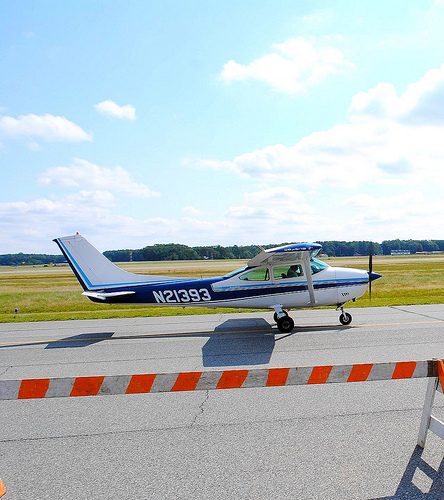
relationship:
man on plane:
[288, 264, 300, 279] [53, 233, 384, 334]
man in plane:
[288, 264, 300, 279] [53, 233, 384, 334]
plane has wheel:
[53, 233, 384, 334] [339, 313, 353, 325]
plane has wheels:
[53, 233, 384, 334] [272, 311, 295, 334]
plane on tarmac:
[53, 233, 384, 334] [2, 308, 444, 500]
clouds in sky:
[1, 99, 139, 146] [3, 2, 213, 100]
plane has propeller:
[53, 233, 384, 334] [370, 241, 373, 294]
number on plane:
[164, 288, 211, 303] [53, 233, 384, 334]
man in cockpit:
[288, 264, 300, 279] [272, 263, 306, 281]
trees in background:
[105, 243, 254, 262] [30, 224, 430, 269]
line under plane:
[2, 318, 443, 347] [53, 233, 384, 334]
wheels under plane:
[272, 311, 295, 334] [53, 233, 384, 334]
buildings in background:
[390, 248, 413, 257] [30, 224, 430, 269]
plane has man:
[53, 233, 384, 334] [288, 264, 300, 279]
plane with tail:
[53, 233, 384, 334] [53, 235, 140, 290]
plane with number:
[53, 233, 384, 334] [164, 288, 211, 303]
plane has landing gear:
[53, 233, 384, 334] [270, 304, 355, 333]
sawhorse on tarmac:
[416, 357, 443, 449] [2, 308, 444, 500]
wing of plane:
[246, 242, 323, 269] [53, 233, 384, 334]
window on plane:
[238, 267, 271, 283] [53, 233, 384, 334]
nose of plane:
[368, 273, 382, 283] [53, 233, 384, 334]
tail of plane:
[53, 235, 140, 290] [53, 233, 384, 334]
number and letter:
[164, 288, 211, 303] [153, 289, 168, 305]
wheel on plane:
[339, 313, 353, 325] [53, 233, 384, 334]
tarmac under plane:
[2, 308, 444, 500] [53, 233, 384, 334]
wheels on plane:
[272, 311, 295, 334] [53, 233, 384, 334]